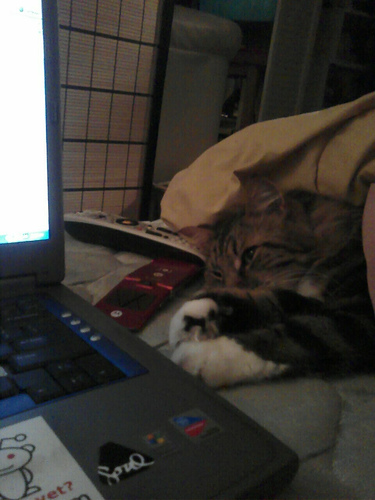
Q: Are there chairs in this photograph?
A: No, there are no chairs.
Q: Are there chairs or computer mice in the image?
A: No, there are no chairs or computer mice.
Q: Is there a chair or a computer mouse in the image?
A: No, there are no chairs or computer mice.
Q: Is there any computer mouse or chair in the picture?
A: No, there are no chairs or computer mice.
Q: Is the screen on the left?
A: Yes, the screen is on the left of the image.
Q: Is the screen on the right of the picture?
A: No, the screen is on the left of the image.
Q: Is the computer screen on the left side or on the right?
A: The screen is on the left of the image.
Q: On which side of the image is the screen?
A: The screen is on the left of the image.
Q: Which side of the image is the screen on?
A: The screen is on the left of the image.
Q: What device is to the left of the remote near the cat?
A: The device is a screen.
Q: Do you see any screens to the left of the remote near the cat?
A: Yes, there is a screen to the left of the remote.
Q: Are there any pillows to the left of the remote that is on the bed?
A: No, there is a screen to the left of the remote.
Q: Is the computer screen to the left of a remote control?
A: Yes, the screen is to the left of a remote control.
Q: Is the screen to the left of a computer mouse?
A: No, the screen is to the left of a remote control.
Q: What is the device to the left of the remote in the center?
A: The device is a screen.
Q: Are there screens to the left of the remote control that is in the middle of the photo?
A: Yes, there is a screen to the left of the remote control.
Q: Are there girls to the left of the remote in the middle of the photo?
A: No, there is a screen to the left of the remote control.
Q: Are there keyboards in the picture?
A: Yes, there is a keyboard.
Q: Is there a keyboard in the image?
A: Yes, there is a keyboard.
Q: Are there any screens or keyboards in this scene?
A: Yes, there is a keyboard.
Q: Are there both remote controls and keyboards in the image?
A: Yes, there are both a keyboard and a remote control.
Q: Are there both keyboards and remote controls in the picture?
A: Yes, there are both a keyboard and a remote control.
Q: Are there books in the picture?
A: No, there are no books.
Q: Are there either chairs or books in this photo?
A: No, there are no books or chairs.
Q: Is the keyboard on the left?
A: Yes, the keyboard is on the left of the image.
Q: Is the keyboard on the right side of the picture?
A: No, the keyboard is on the left of the image.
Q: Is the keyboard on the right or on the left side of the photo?
A: The keyboard is on the left of the image.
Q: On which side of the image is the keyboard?
A: The keyboard is on the left of the image.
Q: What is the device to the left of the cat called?
A: The device is a keyboard.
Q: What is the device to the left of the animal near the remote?
A: The device is a keyboard.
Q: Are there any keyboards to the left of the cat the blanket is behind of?
A: Yes, there is a keyboard to the left of the cat.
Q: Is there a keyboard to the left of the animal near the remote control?
A: Yes, there is a keyboard to the left of the cat.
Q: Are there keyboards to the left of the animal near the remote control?
A: Yes, there is a keyboard to the left of the cat.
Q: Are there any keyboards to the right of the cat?
A: No, the keyboard is to the left of the cat.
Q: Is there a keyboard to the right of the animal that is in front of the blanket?
A: No, the keyboard is to the left of the cat.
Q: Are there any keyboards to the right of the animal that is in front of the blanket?
A: No, the keyboard is to the left of the cat.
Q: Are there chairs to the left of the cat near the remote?
A: No, there is a keyboard to the left of the cat.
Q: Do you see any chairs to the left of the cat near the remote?
A: No, there is a keyboard to the left of the cat.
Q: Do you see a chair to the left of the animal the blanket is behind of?
A: No, there is a keyboard to the left of the cat.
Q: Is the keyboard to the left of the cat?
A: Yes, the keyboard is to the left of the cat.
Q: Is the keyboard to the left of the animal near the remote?
A: Yes, the keyboard is to the left of the cat.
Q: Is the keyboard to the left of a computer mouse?
A: No, the keyboard is to the left of the cat.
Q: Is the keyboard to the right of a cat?
A: No, the keyboard is to the left of a cat.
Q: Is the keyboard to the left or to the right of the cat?
A: The keyboard is to the left of the cat.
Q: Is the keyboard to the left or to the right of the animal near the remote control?
A: The keyboard is to the left of the cat.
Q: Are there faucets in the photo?
A: No, there are no faucets.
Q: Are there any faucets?
A: No, there are no faucets.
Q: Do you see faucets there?
A: No, there are no faucets.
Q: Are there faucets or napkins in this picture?
A: No, there are no faucets or napkins.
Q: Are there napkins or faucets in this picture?
A: No, there are no faucets or napkins.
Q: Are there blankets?
A: Yes, there is a blanket.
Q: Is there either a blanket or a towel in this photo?
A: Yes, there is a blanket.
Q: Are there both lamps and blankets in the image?
A: No, there is a blanket but no lamps.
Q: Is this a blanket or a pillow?
A: This is a blanket.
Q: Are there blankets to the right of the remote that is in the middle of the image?
A: Yes, there is a blanket to the right of the remote.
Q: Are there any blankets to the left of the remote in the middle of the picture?
A: No, the blanket is to the right of the remote control.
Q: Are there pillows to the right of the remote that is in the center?
A: No, there is a blanket to the right of the remote.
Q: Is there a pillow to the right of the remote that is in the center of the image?
A: No, there is a blanket to the right of the remote.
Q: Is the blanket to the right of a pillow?
A: No, the blanket is to the right of the remote.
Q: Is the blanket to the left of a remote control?
A: No, the blanket is to the right of a remote control.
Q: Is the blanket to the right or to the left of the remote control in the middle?
A: The blanket is to the right of the remote.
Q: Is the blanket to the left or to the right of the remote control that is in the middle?
A: The blanket is to the right of the remote.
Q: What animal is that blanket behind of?
A: The blanket is behind the cat.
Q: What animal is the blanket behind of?
A: The blanket is behind the cat.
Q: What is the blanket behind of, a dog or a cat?
A: The blanket is behind a cat.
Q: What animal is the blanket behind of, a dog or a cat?
A: The blanket is behind a cat.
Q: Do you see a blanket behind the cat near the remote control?
A: Yes, there is a blanket behind the cat.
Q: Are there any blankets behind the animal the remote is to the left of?
A: Yes, there is a blanket behind the cat.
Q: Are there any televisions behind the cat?
A: No, there is a blanket behind the cat.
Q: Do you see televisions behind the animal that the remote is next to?
A: No, there is a blanket behind the cat.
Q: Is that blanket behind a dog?
A: No, the blanket is behind the cat.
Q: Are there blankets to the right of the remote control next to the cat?
A: Yes, there is a blanket to the right of the remote.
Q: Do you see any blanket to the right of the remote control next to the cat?
A: Yes, there is a blanket to the right of the remote.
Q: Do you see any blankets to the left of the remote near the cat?
A: No, the blanket is to the right of the remote control.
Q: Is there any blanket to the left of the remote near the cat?
A: No, the blanket is to the right of the remote control.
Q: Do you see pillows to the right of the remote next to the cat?
A: No, there is a blanket to the right of the remote.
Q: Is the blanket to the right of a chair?
A: No, the blanket is to the right of a remote control.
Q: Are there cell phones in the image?
A: Yes, there is a cell phone.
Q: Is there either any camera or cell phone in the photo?
A: Yes, there is a cell phone.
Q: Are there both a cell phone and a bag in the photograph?
A: No, there is a cell phone but no bags.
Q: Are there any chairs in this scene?
A: No, there are no chairs.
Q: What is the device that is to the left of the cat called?
A: The device is a cell phone.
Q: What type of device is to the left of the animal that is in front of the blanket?
A: The device is a cell phone.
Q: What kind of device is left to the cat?
A: The device is a cell phone.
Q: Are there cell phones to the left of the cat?
A: Yes, there is a cell phone to the left of the cat.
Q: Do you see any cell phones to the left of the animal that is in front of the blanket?
A: Yes, there is a cell phone to the left of the cat.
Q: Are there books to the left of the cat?
A: No, there is a cell phone to the left of the cat.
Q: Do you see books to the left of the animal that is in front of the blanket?
A: No, there is a cell phone to the left of the cat.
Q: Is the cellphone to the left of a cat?
A: Yes, the cellphone is to the left of a cat.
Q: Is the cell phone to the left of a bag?
A: No, the cell phone is to the left of a cat.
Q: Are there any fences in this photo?
A: No, there are no fences.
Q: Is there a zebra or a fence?
A: No, there are no fences or zebras.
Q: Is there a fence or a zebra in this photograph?
A: No, there are no fences or zebras.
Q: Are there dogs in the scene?
A: No, there are no dogs.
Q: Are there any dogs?
A: No, there are no dogs.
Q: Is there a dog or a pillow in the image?
A: No, there are no dogs or pillows.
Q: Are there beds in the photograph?
A: Yes, there is a bed.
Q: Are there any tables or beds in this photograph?
A: Yes, there is a bed.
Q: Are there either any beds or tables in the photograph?
A: Yes, there is a bed.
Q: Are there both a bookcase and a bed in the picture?
A: No, there is a bed but no bookcases.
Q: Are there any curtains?
A: No, there are no curtains.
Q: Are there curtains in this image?
A: No, there are no curtains.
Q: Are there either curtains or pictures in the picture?
A: No, there are no curtains or pictures.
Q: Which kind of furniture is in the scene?
A: The furniture is a bed.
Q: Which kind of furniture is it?
A: The piece of furniture is a bed.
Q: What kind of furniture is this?
A: This is a bed.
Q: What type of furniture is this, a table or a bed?
A: This is a bed.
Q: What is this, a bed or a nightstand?
A: This is a bed.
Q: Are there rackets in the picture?
A: No, there are no rackets.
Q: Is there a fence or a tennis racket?
A: No, there are no rackets or fences.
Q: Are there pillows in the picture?
A: No, there are no pillows.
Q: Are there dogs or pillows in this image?
A: No, there are no pillows or dogs.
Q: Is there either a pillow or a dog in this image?
A: No, there are no pillows or dogs.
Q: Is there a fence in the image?
A: No, there are no fences.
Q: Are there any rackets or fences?
A: No, there are no fences or rackets.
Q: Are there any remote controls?
A: Yes, there is a remote control.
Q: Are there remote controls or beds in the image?
A: Yes, there is a remote control.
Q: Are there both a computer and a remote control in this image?
A: Yes, there are both a remote control and a computer.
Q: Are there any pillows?
A: No, there are no pillows.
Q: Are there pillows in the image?
A: No, there are no pillows.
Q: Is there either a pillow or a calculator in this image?
A: No, there are no pillows or calculators.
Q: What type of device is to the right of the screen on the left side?
A: The device is a remote control.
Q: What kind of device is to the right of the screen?
A: The device is a remote control.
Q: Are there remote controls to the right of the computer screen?
A: Yes, there is a remote control to the right of the screen.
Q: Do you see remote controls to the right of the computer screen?
A: Yes, there is a remote control to the right of the screen.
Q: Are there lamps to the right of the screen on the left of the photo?
A: No, there is a remote control to the right of the screen.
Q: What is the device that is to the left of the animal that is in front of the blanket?
A: The device is a remote control.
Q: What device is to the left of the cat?
A: The device is a remote control.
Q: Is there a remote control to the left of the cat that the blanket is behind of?
A: Yes, there is a remote control to the left of the cat.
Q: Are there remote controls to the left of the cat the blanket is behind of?
A: Yes, there is a remote control to the left of the cat.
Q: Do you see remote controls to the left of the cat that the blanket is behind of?
A: Yes, there is a remote control to the left of the cat.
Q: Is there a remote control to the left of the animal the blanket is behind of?
A: Yes, there is a remote control to the left of the cat.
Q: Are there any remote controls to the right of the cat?
A: No, the remote control is to the left of the cat.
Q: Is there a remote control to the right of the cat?
A: No, the remote control is to the left of the cat.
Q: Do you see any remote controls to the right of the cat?
A: No, the remote control is to the left of the cat.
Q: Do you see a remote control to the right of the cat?
A: No, the remote control is to the left of the cat.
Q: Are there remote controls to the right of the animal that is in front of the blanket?
A: No, the remote control is to the left of the cat.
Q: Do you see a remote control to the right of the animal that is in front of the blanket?
A: No, the remote control is to the left of the cat.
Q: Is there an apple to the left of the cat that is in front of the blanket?
A: No, there is a remote control to the left of the cat.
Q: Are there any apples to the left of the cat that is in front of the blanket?
A: No, there is a remote control to the left of the cat.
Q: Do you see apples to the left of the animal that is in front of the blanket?
A: No, there is a remote control to the left of the cat.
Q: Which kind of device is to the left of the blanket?
A: The device is a remote control.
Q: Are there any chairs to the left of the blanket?
A: No, there is a remote control to the left of the blanket.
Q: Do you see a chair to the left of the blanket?
A: No, there is a remote control to the left of the blanket.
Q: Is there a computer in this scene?
A: Yes, there is a computer.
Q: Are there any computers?
A: Yes, there is a computer.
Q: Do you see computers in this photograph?
A: Yes, there is a computer.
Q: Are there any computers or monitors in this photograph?
A: Yes, there is a computer.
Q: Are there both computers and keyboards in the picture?
A: Yes, there are both a computer and a keyboard.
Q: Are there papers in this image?
A: No, there are no papers.